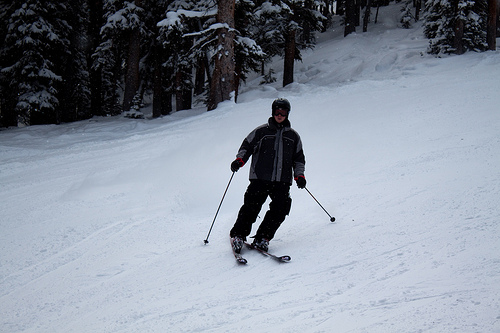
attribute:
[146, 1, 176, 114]
tree — large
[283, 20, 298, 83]
trunk — large, brown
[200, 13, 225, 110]
tree — large, pine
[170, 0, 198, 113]
tree — large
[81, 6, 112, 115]
trunk — large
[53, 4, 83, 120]
tree — large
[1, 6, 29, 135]
tree — large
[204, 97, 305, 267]
person — skating, young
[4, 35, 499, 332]
snow — covering, white, covered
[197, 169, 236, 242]
pole — black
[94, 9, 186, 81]
leaves — green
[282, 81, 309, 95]
pile — snow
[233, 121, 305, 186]
jacket — grey, used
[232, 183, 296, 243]
pants — black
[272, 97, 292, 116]
helmet — black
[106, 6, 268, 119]
trees — covered